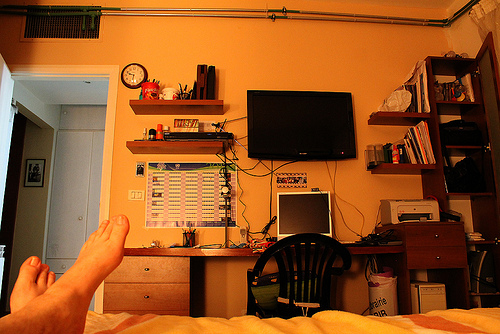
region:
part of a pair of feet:
[78, 225, 98, 282]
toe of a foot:
[111, 212, 127, 234]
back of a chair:
[295, 257, 309, 280]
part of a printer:
[412, 201, 427, 206]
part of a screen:
[292, 102, 312, 114]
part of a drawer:
[133, 265, 153, 285]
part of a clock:
[133, 70, 141, 72]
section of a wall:
[188, 30, 205, 45]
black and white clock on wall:
[112, 56, 150, 97]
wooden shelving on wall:
[127, 65, 235, 160]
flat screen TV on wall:
[236, 72, 363, 184]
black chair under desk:
[237, 225, 350, 325]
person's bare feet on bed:
[16, 211, 159, 332]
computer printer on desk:
[372, 184, 463, 278]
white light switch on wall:
[115, 177, 151, 209]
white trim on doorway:
[11, 53, 121, 215]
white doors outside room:
[34, 96, 114, 253]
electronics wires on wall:
[225, 113, 366, 235]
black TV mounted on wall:
[245, 90, 355, 160]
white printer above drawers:
[380, 196, 436, 221]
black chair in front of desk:
[246, 231, 348, 316]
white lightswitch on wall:
[127, 187, 140, 197]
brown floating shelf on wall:
[128, 98, 223, 113]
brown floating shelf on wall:
[126, 140, 226, 155]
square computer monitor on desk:
[276, 190, 331, 236]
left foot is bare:
[30, 215, 126, 331]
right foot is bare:
[10, 255, 55, 313]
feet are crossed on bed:
[10, 214, 128, 332]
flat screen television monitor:
[248, 83, 355, 157]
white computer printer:
[377, 196, 439, 225]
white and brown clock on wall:
[117, 60, 147, 90]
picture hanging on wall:
[20, 155, 46, 186]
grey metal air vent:
[25, 27, 97, 38]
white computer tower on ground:
[410, 281, 450, 311]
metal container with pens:
[180, 226, 196, 242]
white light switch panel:
[125, 186, 143, 197]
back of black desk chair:
[257, 231, 348, 306]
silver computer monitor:
[275, 193, 334, 237]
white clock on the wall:
[106, 41, 170, 93]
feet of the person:
[4, 203, 131, 333]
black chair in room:
[244, 237, 345, 301]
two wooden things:
[411, 222, 458, 268]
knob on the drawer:
[421, 226, 446, 252]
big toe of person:
[113, 212, 138, 244]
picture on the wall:
[5, 147, 62, 217]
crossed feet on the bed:
[1, 198, 163, 327]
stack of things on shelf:
[371, 121, 436, 183]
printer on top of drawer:
[372, 186, 437, 234]